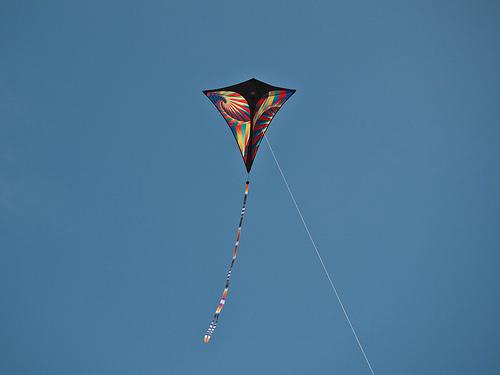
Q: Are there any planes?
A: No, there are no planes.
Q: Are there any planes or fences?
A: No, there are no planes or fences.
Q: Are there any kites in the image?
A: Yes, there is a kite.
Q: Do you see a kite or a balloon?
A: Yes, there is a kite.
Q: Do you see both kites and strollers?
A: No, there is a kite but no strollers.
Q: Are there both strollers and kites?
A: No, there is a kite but no strollers.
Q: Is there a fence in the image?
A: No, there are no fences.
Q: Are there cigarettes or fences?
A: No, there are no fences or cigarettes.